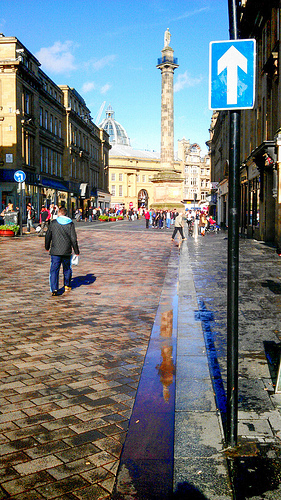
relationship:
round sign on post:
[14, 170, 27, 183] [18, 182, 23, 236]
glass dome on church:
[95, 102, 134, 144] [88, 101, 198, 208]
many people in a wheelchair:
[0, 200, 214, 241] [207, 222, 216, 232]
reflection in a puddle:
[158, 302, 171, 402] [143, 275, 198, 490]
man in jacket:
[45, 207, 79, 296] [42, 216, 81, 256]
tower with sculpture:
[151, 18, 182, 173] [157, 22, 173, 51]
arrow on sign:
[217, 44, 247, 103] [207, 38, 255, 109]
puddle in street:
[111, 229, 181, 499] [7, 227, 208, 493]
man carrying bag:
[45, 207, 79, 296] [67, 252, 83, 265]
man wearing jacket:
[44, 206, 79, 295] [45, 215, 79, 255]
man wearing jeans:
[44, 206, 79, 295] [47, 253, 71, 291]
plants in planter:
[0, 221, 19, 235] [0, 229, 14, 236]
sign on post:
[210, 27, 266, 121] [216, 91, 250, 317]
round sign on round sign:
[14, 170, 27, 183] [11, 168, 28, 183]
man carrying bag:
[44, 206, 79, 295] [69, 253, 79, 265]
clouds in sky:
[38, 34, 126, 79] [2, 0, 230, 159]